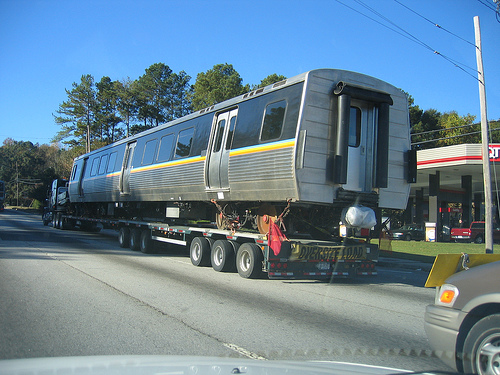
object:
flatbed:
[59, 215, 378, 246]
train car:
[67, 68, 416, 210]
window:
[262, 101, 287, 141]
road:
[0, 208, 455, 374]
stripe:
[230, 138, 296, 151]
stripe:
[229, 141, 295, 156]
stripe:
[417, 156, 482, 166]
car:
[42, 68, 417, 279]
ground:
[0, 209, 500, 354]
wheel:
[140, 229, 155, 253]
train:
[67, 68, 416, 233]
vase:
[190, 237, 215, 267]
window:
[91, 158, 100, 177]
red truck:
[450, 220, 499, 244]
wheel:
[63, 218, 71, 230]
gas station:
[384, 143, 500, 242]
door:
[343, 97, 375, 192]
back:
[285, 69, 334, 191]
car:
[423, 260, 500, 374]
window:
[348, 107, 361, 146]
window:
[175, 127, 195, 157]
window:
[225, 116, 236, 150]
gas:
[439, 208, 462, 241]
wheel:
[55, 217, 60, 229]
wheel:
[128, 228, 142, 251]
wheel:
[236, 243, 268, 279]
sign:
[289, 243, 367, 260]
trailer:
[60, 68, 417, 279]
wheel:
[118, 227, 130, 248]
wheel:
[211, 239, 241, 272]